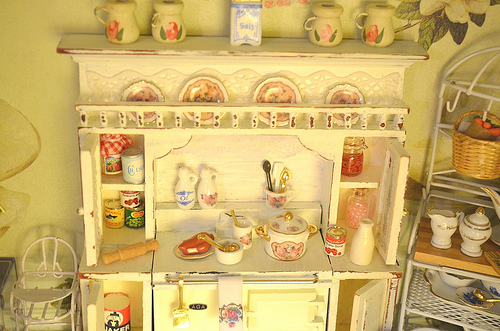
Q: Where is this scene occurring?
A: A child's play kitchen.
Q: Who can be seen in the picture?
A: No one.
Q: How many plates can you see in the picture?
A: 4.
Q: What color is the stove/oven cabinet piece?
A: Antique white.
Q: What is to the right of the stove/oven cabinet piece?
A: A baker's rack.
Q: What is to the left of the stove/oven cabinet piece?
A: A doll high chair.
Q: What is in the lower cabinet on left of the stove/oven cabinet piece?
A: Quaker Oats.